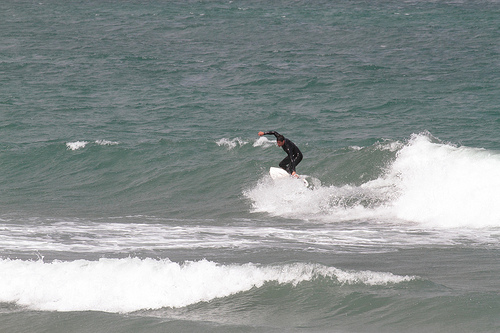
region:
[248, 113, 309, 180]
man surfing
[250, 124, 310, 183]
man surfing in ocean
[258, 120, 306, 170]
man wearing black wet suit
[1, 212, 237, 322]
white and blue waves in ocean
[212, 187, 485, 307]
white and blue waves in ocean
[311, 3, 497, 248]
white and blue waves in ocean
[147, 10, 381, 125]
white and blue waves in ocean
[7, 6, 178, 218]
white and blue waves in ocean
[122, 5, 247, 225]
white and blue waves in ocean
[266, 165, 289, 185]
white surf board used by man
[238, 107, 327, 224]
Person in the ocean.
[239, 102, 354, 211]
Person who is surfing.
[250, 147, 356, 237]
White caps on the waves.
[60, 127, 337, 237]
Waves in the water.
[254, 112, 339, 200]
Black wet suit on the man.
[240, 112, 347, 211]
White surfboard under the man.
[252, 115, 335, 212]
Man participating in a sport.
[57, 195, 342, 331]
Choppy water in the ocean.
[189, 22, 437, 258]
White caps on the ocean waves.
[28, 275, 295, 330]
Water moving towards shore.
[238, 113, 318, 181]
Man wearing black is surfing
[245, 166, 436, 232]
Surfing on the white wave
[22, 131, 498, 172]
Crest of the wave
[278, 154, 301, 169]
Man wearing black wet suit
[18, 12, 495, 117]
Ocean behind man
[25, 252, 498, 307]
Wave in front of man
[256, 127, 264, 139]
Man's right hand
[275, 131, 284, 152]
Person's hair is black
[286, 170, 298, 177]
Man's left hand is white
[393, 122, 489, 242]
White crashed part of wave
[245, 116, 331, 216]
man surfing on a wave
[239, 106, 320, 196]
man in a black wet suit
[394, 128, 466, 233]
white cap on an ocean wave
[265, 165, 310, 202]
white surf board on the ocean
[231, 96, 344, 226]
man hanging ten on the ocean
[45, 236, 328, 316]
waves rolling into the beach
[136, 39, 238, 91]
ripples and waves on the ocean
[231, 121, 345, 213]
man falling off his surf board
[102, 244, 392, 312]
waves crashing to the shore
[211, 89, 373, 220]
man enjoying the ocean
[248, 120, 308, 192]
man surfing in the sea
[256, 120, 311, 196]
man wears a black suit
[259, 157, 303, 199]
snowboard is white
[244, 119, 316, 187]
man has extended arms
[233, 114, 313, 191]
surfer has black hair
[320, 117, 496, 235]
a wave rolling in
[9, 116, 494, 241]
surfer is in a big wave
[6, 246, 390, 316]
small wave crushing in the sand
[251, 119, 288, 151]
right hand of surfer is bend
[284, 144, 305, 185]
left arm is extended